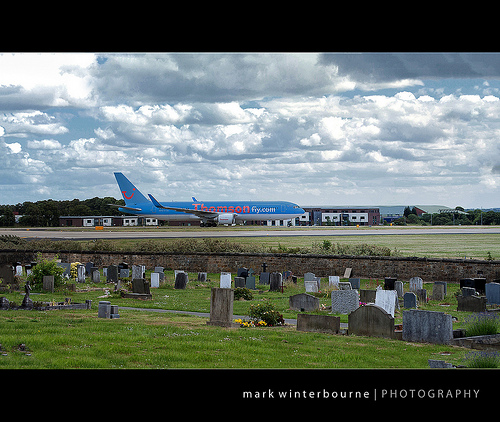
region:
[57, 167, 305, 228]
an airplane is above the runway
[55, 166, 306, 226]
the airplane is blue and white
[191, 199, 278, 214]
the letters on the airplane are red and white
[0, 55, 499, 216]
the sky is blue with white puffy clouds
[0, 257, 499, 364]
a cemetery with headstones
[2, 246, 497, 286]
a wall behind the headstones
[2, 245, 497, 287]
the wall is made of stones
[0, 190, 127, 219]
the trees behind the airplane are green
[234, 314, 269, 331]
yellow flowers are beside the headstone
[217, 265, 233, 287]
the headstone is white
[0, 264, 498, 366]
headstones in a cemetary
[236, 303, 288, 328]
bouquet of flowers near a headstone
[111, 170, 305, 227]
large blue plane on a runway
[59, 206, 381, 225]
row of buildings behind the plane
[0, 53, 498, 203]
thick clouds in the sky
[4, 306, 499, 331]
walkway in the cemetary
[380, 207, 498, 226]
patch of bushes near the buildings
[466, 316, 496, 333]
small patch of grass near a headstone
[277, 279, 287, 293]
small cross near a headstone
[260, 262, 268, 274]
small cross atop a headstone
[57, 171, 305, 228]
A plane on a runway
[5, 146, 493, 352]
A cemetery next to an airport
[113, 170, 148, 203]
Tail fin of an airplane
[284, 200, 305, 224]
Cockpit of an airplane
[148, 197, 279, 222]
Fuselage of an airplane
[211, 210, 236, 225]
Air plane jet engine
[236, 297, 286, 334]
A bush of flowers growing in grass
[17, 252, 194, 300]
A cluster of headstones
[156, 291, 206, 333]
Lawn bisected by a path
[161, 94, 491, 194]
A cloudy, overcast sky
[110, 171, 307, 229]
blue and white jumbo jet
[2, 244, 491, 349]
old graveyard with stone wall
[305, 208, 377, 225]
row of apartment buildings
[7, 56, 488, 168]
sky filled with fluffy white clouds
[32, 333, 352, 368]
well manicured green grass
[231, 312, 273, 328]
freshly planted grave flowers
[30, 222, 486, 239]
paved runway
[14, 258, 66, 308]
small shrub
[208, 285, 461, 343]
row of old tombstones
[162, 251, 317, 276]
old stone wall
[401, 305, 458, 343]
gray square headstone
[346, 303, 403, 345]
old gray semi circular headstone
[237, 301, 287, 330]
cluster of yellow and green flowers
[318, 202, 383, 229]
brownstone building with white facade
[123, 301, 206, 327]
portion of road in cemetery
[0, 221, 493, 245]
long paved airport runway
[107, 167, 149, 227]
blue tail of airplane with circular red symbol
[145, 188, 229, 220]
gray flaps on airplane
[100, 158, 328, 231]
large light blue and white airplane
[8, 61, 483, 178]
cluster of different size clouds